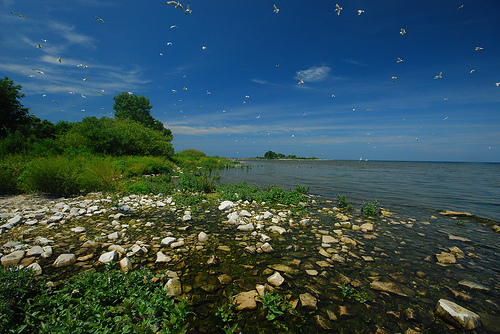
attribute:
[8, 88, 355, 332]
scenery — green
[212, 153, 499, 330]
water — the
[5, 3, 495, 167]
sky — blue, clear, the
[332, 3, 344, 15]
bird — flying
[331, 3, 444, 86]
birds — flying, some, white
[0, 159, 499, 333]
water — a, body, group, dark, calm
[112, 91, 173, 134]
tree — old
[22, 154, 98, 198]
bush — little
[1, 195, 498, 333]
rocks — wet, gray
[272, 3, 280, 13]
bird — flying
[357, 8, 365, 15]
bird — white, flying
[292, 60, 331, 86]
cloud — white, thin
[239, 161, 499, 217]
ocean — the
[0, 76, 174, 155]
trees — dark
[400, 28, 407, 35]
bird — flying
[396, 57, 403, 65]
bird — flying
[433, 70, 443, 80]
bird — flying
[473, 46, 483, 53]
bird — flying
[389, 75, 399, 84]
bird — flying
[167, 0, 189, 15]
bird — flying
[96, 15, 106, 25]
bird — flying